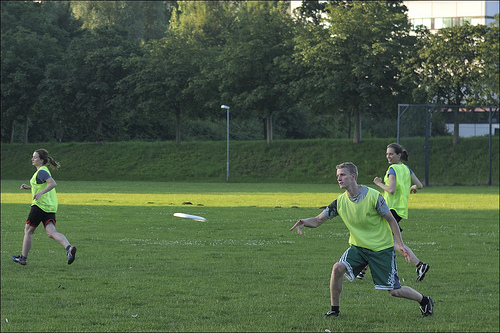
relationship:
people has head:
[283, 162, 437, 320] [332, 160, 362, 190]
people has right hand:
[283, 162, 437, 320] [290, 218, 308, 237]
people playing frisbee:
[12, 143, 441, 319] [172, 208, 206, 226]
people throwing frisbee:
[283, 162, 437, 320] [172, 208, 206, 226]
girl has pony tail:
[11, 143, 79, 268] [35, 149, 63, 171]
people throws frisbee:
[283, 162, 437, 320] [172, 208, 206, 226]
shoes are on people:
[393, 208, 407, 235] [283, 162, 437, 320]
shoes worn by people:
[314, 299, 434, 322] [283, 162, 437, 320]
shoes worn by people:
[393, 208, 407, 235] [283, 162, 437, 320]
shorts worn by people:
[339, 240, 404, 292] [283, 162, 437, 320]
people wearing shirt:
[283, 162, 437, 320] [336, 192, 396, 251]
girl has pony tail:
[11, 147, 76, 266] [35, 149, 63, 171]